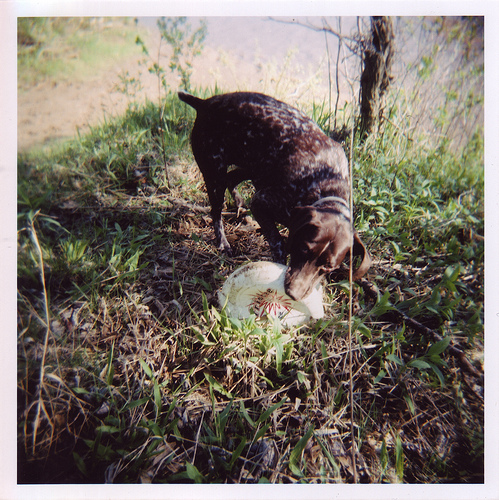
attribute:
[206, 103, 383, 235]
dog — playing, biting, brown, looking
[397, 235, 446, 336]
grass — dead, dry, green, brown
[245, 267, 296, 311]
frisbee — white